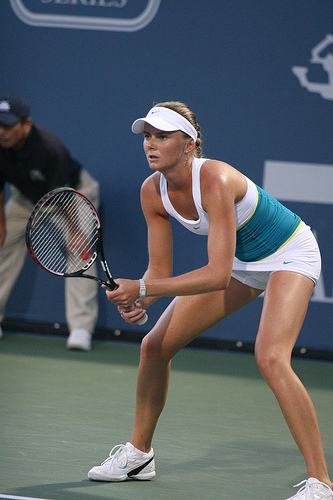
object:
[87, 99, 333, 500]
woman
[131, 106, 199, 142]
hat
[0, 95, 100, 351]
man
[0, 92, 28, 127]
hat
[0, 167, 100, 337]
pants